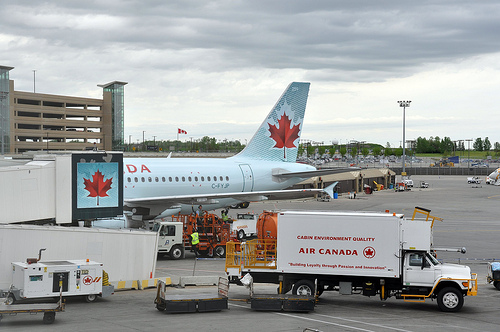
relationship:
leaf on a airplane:
[265, 104, 300, 153] [122, 83, 365, 221]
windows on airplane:
[103, 161, 263, 205] [31, 78, 335, 225]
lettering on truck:
[286, 232, 386, 270] [270, 206, 478, 314]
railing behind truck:
[218, 234, 282, 271] [270, 206, 478, 314]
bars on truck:
[378, 270, 476, 304] [221, 211, 476, 312]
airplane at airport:
[59, 67, 356, 234] [2, 79, 498, 330]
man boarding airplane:
[188, 230, 199, 260] [122, 83, 365, 221]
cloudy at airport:
[5, 0, 497, 143] [2, 61, 482, 325]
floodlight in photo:
[396, 97, 411, 178] [3, 2, 495, 327]